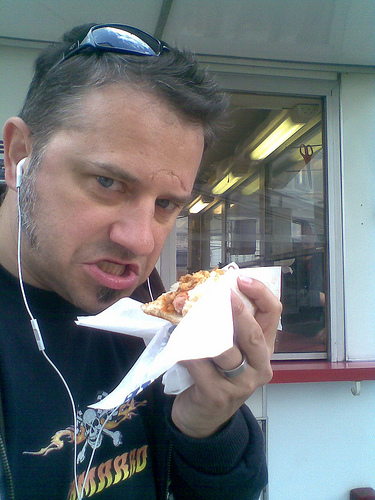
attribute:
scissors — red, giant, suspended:
[298, 143, 313, 188]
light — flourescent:
[247, 116, 302, 160]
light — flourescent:
[211, 167, 243, 195]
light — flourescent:
[183, 199, 219, 217]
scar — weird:
[148, 166, 191, 192]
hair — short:
[20, 24, 220, 163]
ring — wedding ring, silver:
[222, 355, 245, 377]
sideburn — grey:
[21, 147, 40, 246]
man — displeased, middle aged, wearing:
[0, 20, 283, 497]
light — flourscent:
[252, 103, 328, 163]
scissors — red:
[295, 141, 319, 191]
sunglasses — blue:
[44, 22, 172, 74]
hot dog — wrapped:
[139, 269, 216, 326]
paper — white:
[111, 253, 279, 378]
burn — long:
[15, 135, 49, 242]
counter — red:
[267, 357, 368, 393]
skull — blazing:
[75, 407, 108, 450]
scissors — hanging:
[296, 140, 317, 188]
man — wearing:
[6, 36, 183, 297]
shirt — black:
[0, 267, 150, 496]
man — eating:
[10, 10, 286, 434]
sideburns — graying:
[17, 171, 44, 243]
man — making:
[3, 128, 211, 455]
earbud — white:
[15, 154, 29, 187]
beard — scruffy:
[96, 286, 121, 305]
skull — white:
[74, 399, 123, 452]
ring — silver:
[213, 343, 251, 379]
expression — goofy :
[294, 238, 317, 259]